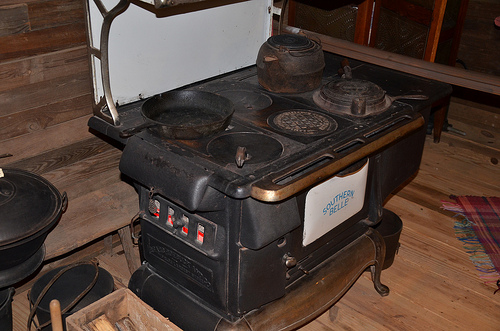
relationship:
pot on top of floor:
[27, 265, 115, 330] [7, 89, 496, 327]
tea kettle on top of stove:
[257, 34, 327, 95] [88, 59, 427, 330]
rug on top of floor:
[437, 195, 498, 294] [7, 89, 496, 327]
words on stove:
[288, 164, 383, 246] [88, 59, 427, 330]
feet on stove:
[369, 254, 390, 297] [88, 59, 427, 330]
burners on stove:
[201, 72, 339, 145] [88, 59, 427, 330]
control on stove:
[266, 245, 325, 281] [88, 59, 427, 330]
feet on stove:
[365, 254, 403, 304] [88, 59, 427, 330]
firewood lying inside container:
[112, 315, 140, 329] [61, 284, 183, 328]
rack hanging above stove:
[129, 1, 252, 18] [88, 59, 427, 330]